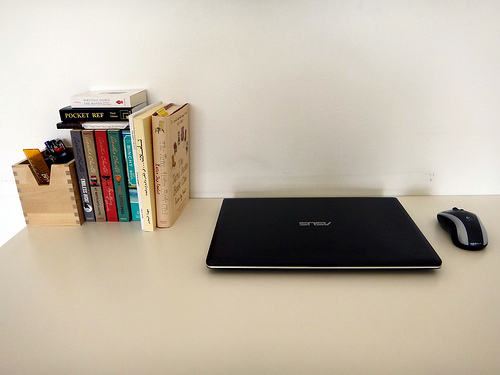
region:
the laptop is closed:
[204, 189, 447, 291]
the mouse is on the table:
[435, 188, 492, 257]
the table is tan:
[73, 263, 153, 325]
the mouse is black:
[437, 190, 496, 267]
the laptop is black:
[58, 102, 134, 124]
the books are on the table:
[68, 108, 191, 243]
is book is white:
[67, 87, 134, 105]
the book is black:
[205, 184, 442, 280]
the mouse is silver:
[437, 202, 489, 254]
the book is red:
[99, 129, 121, 227]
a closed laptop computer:
[196, 190, 443, 275]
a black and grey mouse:
[435, 205, 489, 253]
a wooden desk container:
[11, 139, 83, 228]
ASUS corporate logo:
[294, 217, 331, 228]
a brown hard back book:
[143, 103, 194, 228]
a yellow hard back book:
[131, 101, 156, 232]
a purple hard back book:
[68, 129, 92, 224]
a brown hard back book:
[78, 131, 105, 218]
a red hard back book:
[94, 127, 116, 224]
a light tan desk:
[5, 194, 497, 368]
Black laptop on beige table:
[200, 193, 442, 273]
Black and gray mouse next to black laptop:
[435, 202, 487, 251]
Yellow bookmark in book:
[152, 105, 174, 118]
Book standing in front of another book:
[152, 101, 195, 227]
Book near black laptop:
[150, 97, 196, 227]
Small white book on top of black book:
[68, 89, 148, 107]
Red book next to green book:
[94, 128, 117, 220]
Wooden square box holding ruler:
[10, 141, 85, 225]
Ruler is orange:
[20, 140, 51, 185]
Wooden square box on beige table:
[9, 147, 83, 227]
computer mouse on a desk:
[430, 194, 494, 257]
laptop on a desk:
[195, 187, 452, 297]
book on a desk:
[147, 95, 206, 247]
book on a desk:
[130, 96, 172, 236]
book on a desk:
[62, 83, 156, 113]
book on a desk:
[54, 97, 150, 127]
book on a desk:
[119, 127, 139, 228]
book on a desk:
[101, 126, 131, 228]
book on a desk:
[73, 121, 109, 233]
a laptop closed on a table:
[177, 136, 428, 293]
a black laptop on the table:
[151, 125, 498, 357]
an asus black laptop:
[124, 96, 464, 246]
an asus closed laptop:
[204, 152, 479, 346]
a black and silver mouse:
[398, 166, 493, 251]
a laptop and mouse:
[111, 105, 472, 331]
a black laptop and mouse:
[182, 132, 442, 306]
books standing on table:
[22, 55, 308, 322]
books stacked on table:
[0, 35, 285, 298]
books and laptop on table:
[60, 35, 499, 320]